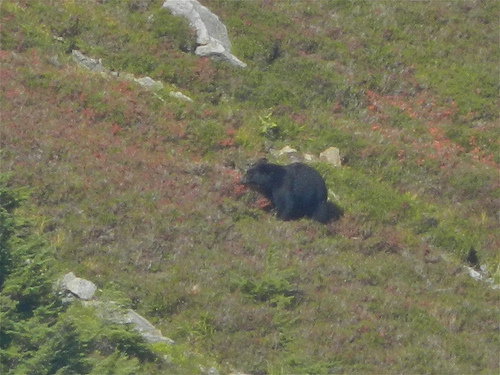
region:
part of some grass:
[288, 295, 369, 351]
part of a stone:
[66, 272, 91, 301]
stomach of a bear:
[301, 174, 326, 199]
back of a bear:
[286, 167, 312, 187]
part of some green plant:
[343, 177, 414, 232]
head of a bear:
[237, 163, 271, 190]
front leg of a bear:
[271, 192, 292, 217]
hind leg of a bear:
[304, 195, 329, 225]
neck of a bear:
[260, 167, 282, 205]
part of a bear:
[242, 162, 322, 225]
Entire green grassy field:
[0, 0, 499, 374]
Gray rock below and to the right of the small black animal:
[51, 269, 173, 354]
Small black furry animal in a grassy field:
[242, 155, 348, 226]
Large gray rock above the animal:
[146, 0, 247, 67]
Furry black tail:
[315, 199, 342, 225]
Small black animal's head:
[243, 159, 279, 194]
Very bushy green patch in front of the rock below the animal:
[1, 191, 213, 374]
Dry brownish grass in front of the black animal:
[0, 52, 245, 222]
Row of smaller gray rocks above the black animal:
[65, 34, 341, 166]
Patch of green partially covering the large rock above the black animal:
[139, 6, 198, 54]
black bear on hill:
[237, 145, 336, 224]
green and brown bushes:
[8, 208, 58, 367]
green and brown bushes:
[193, 234, 405, 373]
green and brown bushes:
[20, 99, 182, 270]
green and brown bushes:
[278, 7, 479, 122]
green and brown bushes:
[362, 65, 486, 226]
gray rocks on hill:
[281, 135, 358, 163]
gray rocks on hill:
[43, 255, 176, 352]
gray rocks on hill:
[53, 30, 184, 130]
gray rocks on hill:
[150, 2, 253, 77]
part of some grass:
[320, 268, 365, 315]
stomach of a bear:
[291, 186, 315, 216]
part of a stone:
[129, 320, 159, 350]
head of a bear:
[232, 157, 261, 187]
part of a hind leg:
[315, 204, 327, 228]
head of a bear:
[254, 156, 273, 185]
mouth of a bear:
[232, 172, 249, 192]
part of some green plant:
[387, 195, 435, 245]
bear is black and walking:
[225, 146, 360, 261]